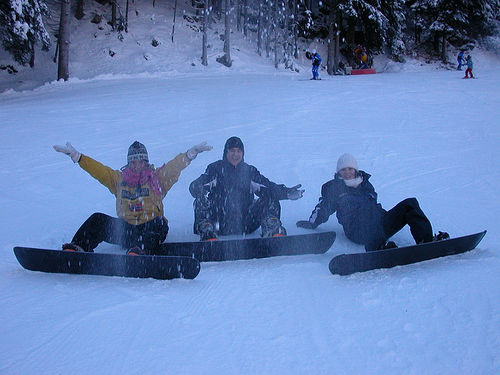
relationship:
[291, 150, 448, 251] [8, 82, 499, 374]
snowboarders sitting in snow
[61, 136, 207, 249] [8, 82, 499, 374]
woman sitting in snow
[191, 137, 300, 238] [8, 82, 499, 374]
man sitting in snow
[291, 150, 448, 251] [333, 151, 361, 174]
snowboarders wearing a cap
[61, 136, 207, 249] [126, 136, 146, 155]
woman wearing a cap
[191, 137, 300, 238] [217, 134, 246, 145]
man wearing a cap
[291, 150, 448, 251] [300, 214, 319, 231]
snowboarders wearing gloves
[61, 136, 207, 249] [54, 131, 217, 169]
woman wearing gloves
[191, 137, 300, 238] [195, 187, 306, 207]
man wearing gloves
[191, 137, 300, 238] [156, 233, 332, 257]
man on a snowboard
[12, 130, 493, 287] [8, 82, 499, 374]
snowboarders sitting in snow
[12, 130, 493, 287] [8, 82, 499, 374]
snowboarders playing in snow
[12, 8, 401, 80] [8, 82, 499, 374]
snow falling onto snow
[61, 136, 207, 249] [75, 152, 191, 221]
woman wearing sweatshirt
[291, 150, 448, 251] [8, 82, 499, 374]
snowboarders laying in snow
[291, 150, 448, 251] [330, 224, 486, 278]
snowboarders with a snowboard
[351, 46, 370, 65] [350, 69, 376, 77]
person on an innertube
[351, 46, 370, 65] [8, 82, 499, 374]
person in snow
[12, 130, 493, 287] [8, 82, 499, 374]
snowboarders in snow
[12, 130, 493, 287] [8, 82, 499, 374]
snowboarders on snow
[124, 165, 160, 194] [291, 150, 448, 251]
scarf of snowboarders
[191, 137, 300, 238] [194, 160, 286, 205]
man wearing coat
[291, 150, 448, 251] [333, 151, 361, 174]
snowboarders wearing cap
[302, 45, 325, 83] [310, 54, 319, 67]
person wearing uniform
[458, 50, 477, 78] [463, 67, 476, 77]
person wearing pants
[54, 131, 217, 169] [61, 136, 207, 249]
gloves of woman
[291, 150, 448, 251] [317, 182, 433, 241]
snowboarders wearing suit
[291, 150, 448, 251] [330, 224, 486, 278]
snowboarders wearing a snowboard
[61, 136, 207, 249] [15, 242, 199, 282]
woman wearing a snowboard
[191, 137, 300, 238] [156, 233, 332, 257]
man wearing a snowboard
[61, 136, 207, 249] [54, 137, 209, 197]
woman has arms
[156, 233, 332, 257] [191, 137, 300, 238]
snowboard of man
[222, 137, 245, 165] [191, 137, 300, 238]
head of man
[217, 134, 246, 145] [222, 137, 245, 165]
cap on head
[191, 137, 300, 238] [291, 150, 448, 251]
man beside snowboarders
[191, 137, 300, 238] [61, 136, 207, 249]
man beside woman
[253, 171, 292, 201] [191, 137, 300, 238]
arm of man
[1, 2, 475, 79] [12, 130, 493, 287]
trees behind snowboarders